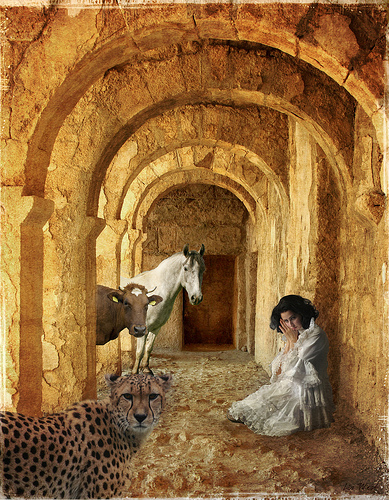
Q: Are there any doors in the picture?
A: Yes, there is a door.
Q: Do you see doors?
A: Yes, there is a door.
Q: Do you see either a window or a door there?
A: Yes, there is a door.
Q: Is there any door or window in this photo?
A: Yes, there is a door.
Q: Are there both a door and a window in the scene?
A: No, there is a door but no windows.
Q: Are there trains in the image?
A: No, there are no trains.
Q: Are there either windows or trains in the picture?
A: No, there are no trains or windows.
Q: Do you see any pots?
A: No, there are no pots.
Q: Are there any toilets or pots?
A: No, there are no pots or toilets.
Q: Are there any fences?
A: No, there are no fences.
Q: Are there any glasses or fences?
A: No, there are no fences or glasses.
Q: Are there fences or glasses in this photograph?
A: No, there are no fences or glasses.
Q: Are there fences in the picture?
A: No, there are no fences.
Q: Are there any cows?
A: Yes, there is a cow.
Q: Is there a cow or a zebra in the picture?
A: Yes, there is a cow.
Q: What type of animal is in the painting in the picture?
A: The animal is a cow.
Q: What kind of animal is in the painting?
A: The animal is a cow.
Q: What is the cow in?
A: The cow is in the painting.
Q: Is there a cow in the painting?
A: Yes, there is a cow in the painting.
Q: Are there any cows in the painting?
A: Yes, there is a cow in the painting.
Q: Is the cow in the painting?
A: Yes, the cow is in the painting.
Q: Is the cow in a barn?
A: No, the cow is in the painting.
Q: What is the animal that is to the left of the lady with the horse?
A: The animal is a cow.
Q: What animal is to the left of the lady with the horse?
A: The animal is a cow.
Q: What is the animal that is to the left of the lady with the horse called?
A: The animal is a cow.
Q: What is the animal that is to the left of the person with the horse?
A: The animal is a cow.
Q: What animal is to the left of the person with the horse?
A: The animal is a cow.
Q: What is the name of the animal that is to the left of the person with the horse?
A: The animal is a cow.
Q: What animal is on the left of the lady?
A: The animal is a cow.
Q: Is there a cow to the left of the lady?
A: Yes, there is a cow to the left of the lady.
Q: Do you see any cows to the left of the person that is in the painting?
A: Yes, there is a cow to the left of the lady.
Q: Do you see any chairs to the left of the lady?
A: No, there is a cow to the left of the lady.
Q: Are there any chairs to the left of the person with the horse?
A: No, there is a cow to the left of the lady.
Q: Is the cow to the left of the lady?
A: Yes, the cow is to the left of the lady.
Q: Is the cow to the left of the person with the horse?
A: Yes, the cow is to the left of the lady.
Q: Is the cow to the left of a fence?
A: No, the cow is to the left of the lady.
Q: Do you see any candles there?
A: No, there are no candles.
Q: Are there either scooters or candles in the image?
A: No, there are no candles or scooters.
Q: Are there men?
A: No, there are no men.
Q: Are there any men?
A: No, there are no men.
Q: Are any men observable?
A: No, there are no men.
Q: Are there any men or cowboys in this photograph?
A: No, there are no men or cowboys.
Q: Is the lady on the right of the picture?
A: Yes, the lady is on the right of the image.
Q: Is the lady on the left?
A: No, the lady is on the right of the image.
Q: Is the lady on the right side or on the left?
A: The lady is on the right of the image.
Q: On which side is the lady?
A: The lady is on the right of the image.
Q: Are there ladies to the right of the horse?
A: Yes, there is a lady to the right of the horse.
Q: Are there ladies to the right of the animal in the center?
A: Yes, there is a lady to the right of the horse.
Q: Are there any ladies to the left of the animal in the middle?
A: No, the lady is to the right of the horse.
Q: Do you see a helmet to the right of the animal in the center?
A: No, there is a lady to the right of the horse.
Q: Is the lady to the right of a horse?
A: Yes, the lady is to the right of a horse.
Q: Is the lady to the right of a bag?
A: No, the lady is to the right of a horse.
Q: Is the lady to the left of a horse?
A: No, the lady is to the right of a horse.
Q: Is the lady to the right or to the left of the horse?
A: The lady is to the right of the horse.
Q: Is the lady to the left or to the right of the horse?
A: The lady is to the right of the horse.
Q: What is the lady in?
A: The lady is in the painting.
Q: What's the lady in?
A: The lady is in the painting.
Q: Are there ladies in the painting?
A: Yes, there is a lady in the painting.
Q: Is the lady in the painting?
A: Yes, the lady is in the painting.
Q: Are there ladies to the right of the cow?
A: Yes, there is a lady to the right of the cow.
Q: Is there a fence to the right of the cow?
A: No, there is a lady to the right of the cow.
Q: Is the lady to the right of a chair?
A: No, the lady is to the right of the cow.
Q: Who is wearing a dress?
A: The lady is wearing a dress.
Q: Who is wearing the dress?
A: The lady is wearing a dress.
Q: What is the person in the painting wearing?
A: The lady is wearing a dress.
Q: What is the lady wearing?
A: The lady is wearing a dress.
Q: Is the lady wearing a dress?
A: Yes, the lady is wearing a dress.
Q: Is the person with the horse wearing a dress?
A: Yes, the lady is wearing a dress.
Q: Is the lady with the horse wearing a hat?
A: No, the lady is wearing a dress.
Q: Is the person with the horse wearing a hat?
A: No, the lady is wearing a dress.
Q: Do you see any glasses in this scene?
A: No, there are no glasses.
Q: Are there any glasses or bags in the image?
A: No, there are no glasses or bags.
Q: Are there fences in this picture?
A: No, there are no fences.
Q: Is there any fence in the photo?
A: No, there are no fences.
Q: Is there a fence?
A: No, there are no fences.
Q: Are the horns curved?
A: Yes, the horns are curved.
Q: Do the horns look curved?
A: Yes, the horns are curved.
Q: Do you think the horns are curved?
A: Yes, the horns are curved.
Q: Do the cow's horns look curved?
A: Yes, the horns are curved.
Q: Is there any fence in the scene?
A: No, there are no fences.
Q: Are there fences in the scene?
A: No, there are no fences.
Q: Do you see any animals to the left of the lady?
A: Yes, there are animals to the left of the lady.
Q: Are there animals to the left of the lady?
A: Yes, there are animals to the left of the lady.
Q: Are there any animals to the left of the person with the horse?
A: Yes, there are animals to the left of the lady.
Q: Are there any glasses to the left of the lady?
A: No, there are animals to the left of the lady.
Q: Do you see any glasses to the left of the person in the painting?
A: No, there are animals to the left of the lady.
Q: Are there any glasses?
A: No, there are no glasses.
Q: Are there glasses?
A: No, there are no glasses.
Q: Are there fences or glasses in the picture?
A: No, there are no glasses or fences.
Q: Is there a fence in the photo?
A: No, there are no fences.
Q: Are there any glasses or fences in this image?
A: No, there are no fences or glasses.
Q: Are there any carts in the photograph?
A: No, there are no carts.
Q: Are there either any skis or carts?
A: No, there are no carts or skis.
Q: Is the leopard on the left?
A: Yes, the leopard is on the left of the image.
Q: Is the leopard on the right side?
A: No, the leopard is on the left of the image.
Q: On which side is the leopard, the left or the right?
A: The leopard is on the left of the image.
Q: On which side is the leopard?
A: The leopard is on the left of the image.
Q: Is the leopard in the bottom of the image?
A: Yes, the leopard is in the bottom of the image.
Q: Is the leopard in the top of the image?
A: No, the leopard is in the bottom of the image.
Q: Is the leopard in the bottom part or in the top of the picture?
A: The leopard is in the bottom of the image.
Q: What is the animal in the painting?
A: The animal is a leopard.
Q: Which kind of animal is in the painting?
A: The animal is a leopard.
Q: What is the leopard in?
A: The leopard is in the painting.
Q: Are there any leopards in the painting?
A: Yes, there is a leopard in the painting.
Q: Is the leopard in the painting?
A: Yes, the leopard is in the painting.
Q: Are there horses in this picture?
A: Yes, there is a horse.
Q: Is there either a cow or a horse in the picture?
A: Yes, there is a horse.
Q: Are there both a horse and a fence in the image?
A: No, there is a horse but no fences.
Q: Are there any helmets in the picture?
A: No, there are no helmets.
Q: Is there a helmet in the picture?
A: No, there are no helmets.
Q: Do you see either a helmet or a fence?
A: No, there are no helmets or fences.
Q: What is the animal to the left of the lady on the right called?
A: The animal is a horse.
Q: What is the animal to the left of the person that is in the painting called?
A: The animal is a horse.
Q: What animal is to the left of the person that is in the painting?
A: The animal is a horse.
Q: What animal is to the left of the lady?
A: The animal is a horse.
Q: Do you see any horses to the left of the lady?
A: Yes, there is a horse to the left of the lady.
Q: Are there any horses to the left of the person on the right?
A: Yes, there is a horse to the left of the lady.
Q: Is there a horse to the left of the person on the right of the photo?
A: Yes, there is a horse to the left of the lady.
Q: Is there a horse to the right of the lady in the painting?
A: No, the horse is to the left of the lady.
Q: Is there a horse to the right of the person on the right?
A: No, the horse is to the left of the lady.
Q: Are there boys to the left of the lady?
A: No, there is a horse to the left of the lady.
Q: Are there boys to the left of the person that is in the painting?
A: No, there is a horse to the left of the lady.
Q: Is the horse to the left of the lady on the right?
A: Yes, the horse is to the left of the lady.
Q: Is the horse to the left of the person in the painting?
A: Yes, the horse is to the left of the lady.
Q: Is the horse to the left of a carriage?
A: No, the horse is to the left of the lady.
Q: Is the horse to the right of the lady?
A: No, the horse is to the left of the lady.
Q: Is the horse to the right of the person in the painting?
A: No, the horse is to the left of the lady.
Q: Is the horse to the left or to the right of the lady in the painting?
A: The horse is to the left of the lady.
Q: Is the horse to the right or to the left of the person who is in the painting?
A: The horse is to the left of the lady.